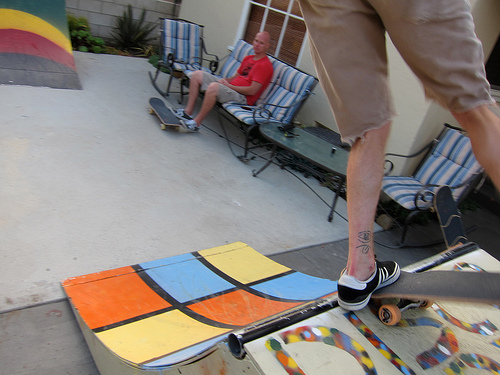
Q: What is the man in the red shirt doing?
A: Sitting in a chair.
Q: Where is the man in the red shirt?
A: On a patio.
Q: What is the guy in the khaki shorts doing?
A: Skateboarding.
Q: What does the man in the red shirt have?
A: A skateboard.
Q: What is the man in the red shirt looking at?
A: The skateboarder.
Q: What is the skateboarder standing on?
A: A ramp.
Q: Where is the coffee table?
A: A patio.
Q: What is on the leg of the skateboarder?
A: A tattoo.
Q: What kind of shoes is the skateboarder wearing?
A: Sneakers.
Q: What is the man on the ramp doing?
A: A skateboard trick.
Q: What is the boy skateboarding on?
A: Ramp.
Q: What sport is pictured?
A: Skateboarding.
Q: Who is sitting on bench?
A: Man in red.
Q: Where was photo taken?
A: Patio.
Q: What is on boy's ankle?
A: Tattoo.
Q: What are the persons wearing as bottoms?
A: Shorts.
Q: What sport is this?
A: Skateboarding.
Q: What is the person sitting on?
A: A chair.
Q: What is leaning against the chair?
A: A skateboard.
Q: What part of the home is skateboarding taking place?
A: Backyard.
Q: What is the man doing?
A: Skateboarding.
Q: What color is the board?
A: Gray.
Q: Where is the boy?
A: On the skateboard.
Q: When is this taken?
A: During the daytime.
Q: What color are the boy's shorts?
A: Khaki.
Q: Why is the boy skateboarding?
A: For fun.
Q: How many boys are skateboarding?
A: One.